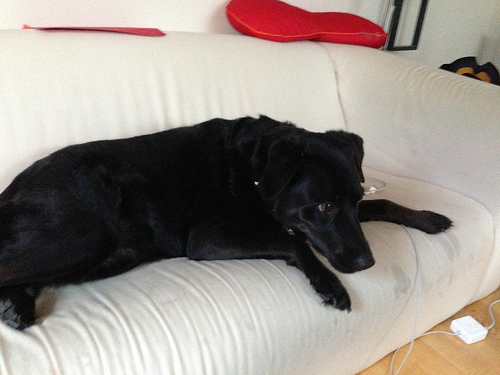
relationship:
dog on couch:
[3, 112, 458, 331] [2, 23, 500, 372]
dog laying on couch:
[3, 112, 458, 331] [2, 23, 500, 372]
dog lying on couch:
[3, 112, 458, 331] [2, 23, 500, 372]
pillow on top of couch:
[225, 2, 393, 47] [2, 23, 500, 372]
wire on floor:
[366, 173, 499, 367] [360, 287, 500, 373]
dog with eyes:
[3, 112, 458, 331] [311, 191, 364, 213]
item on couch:
[23, 23, 168, 37] [2, 23, 500, 372]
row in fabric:
[34, 47, 386, 372] [0, 35, 499, 375]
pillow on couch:
[225, 2, 393, 47] [2, 23, 500, 372]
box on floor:
[453, 314, 488, 348] [360, 287, 500, 373]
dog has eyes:
[3, 112, 458, 331] [311, 191, 364, 213]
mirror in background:
[383, 1, 437, 57] [3, 2, 499, 141]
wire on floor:
[366, 173, 448, 367] [360, 287, 500, 373]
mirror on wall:
[383, 1, 437, 57] [5, 1, 500, 90]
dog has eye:
[3, 112, 458, 331] [316, 200, 333, 214]